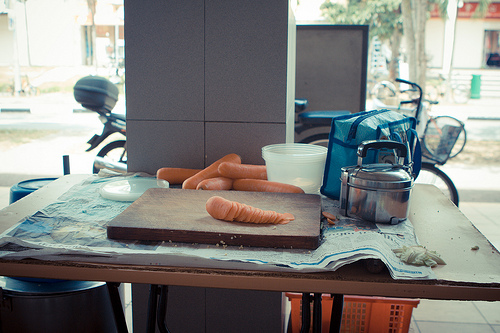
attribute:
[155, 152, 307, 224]
carrots — red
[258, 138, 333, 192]
container — plastic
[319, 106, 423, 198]
bag — light blue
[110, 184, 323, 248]
cutting board — wooden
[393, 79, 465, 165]
bicycle — light grey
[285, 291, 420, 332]
laundry basket — bright orange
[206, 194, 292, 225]
carrot — cut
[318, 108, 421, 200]
blue bag — small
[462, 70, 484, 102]
can — green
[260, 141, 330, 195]
container — clear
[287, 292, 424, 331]
crate — orange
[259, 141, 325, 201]
container — white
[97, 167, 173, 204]
lid — small, clear, plastic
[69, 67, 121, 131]
helmet carrier — black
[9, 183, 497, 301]
table — big, brown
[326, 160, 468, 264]
surface — silver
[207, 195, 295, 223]
chopped carrot — orange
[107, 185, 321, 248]
board — brown, wooden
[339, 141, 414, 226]
pot — grey, metal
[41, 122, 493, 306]
table — brown, wooden